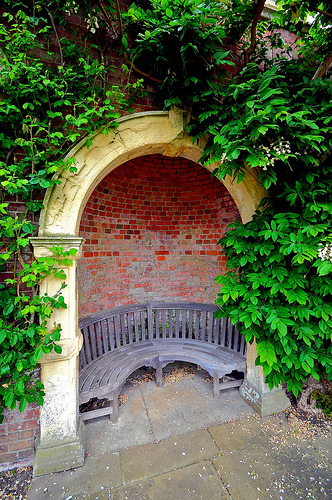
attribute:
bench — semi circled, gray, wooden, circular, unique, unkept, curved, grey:
[49, 302, 287, 418]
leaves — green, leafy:
[0, 10, 331, 405]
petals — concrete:
[2, 422, 324, 472]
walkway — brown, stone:
[3, 386, 331, 496]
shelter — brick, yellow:
[25, 92, 309, 450]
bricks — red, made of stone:
[92, 187, 228, 283]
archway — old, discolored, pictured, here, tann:
[32, 105, 327, 442]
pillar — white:
[14, 161, 115, 474]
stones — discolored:
[35, 92, 312, 476]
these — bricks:
[30, 429, 303, 495]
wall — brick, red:
[63, 167, 249, 302]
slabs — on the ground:
[30, 425, 332, 466]